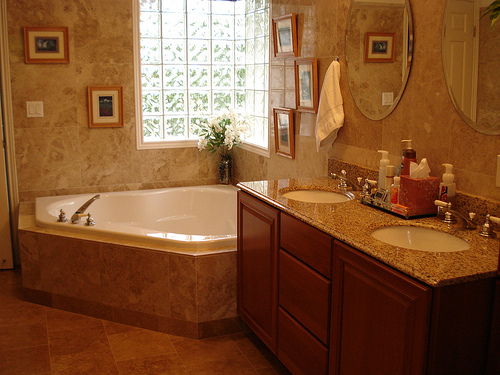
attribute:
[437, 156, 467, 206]
bottle — plastic, hand soap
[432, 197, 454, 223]
knob — white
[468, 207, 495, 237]
knob — white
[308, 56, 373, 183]
towel — white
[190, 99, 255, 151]
flowers — white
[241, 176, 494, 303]
sink — granite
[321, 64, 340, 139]
towel — white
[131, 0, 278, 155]
window — glass block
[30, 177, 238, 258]
bath tub — white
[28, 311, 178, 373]
tiles — brown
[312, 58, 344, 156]
towel — white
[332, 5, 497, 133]
mirrors — round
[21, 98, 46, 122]
switches — light, push in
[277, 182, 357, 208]
sink — white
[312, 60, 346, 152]
towel — white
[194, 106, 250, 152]
flowers — white